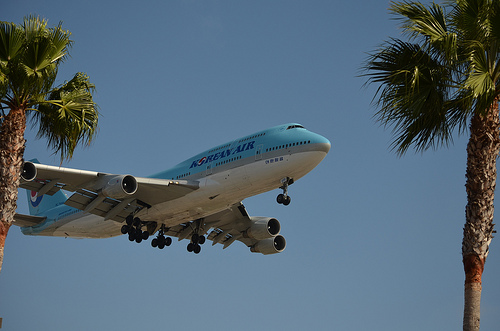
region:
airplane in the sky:
[0, 108, 337, 276]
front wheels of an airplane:
[271, 172, 298, 211]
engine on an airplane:
[94, 169, 146, 203]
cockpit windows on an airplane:
[281, 120, 312, 136]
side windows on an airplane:
[212, 149, 249, 169]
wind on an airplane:
[11, 150, 203, 227]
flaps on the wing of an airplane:
[58, 184, 151, 234]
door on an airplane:
[249, 141, 268, 168]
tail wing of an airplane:
[5, 205, 45, 233]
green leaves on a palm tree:
[35, 66, 102, 169]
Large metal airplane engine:
[97, 163, 149, 207]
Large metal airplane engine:
[237, 201, 282, 244]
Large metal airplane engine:
[246, 232, 290, 259]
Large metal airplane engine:
[10, 156, 52, 192]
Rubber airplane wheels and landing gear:
[262, 175, 301, 214]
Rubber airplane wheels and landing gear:
[177, 219, 211, 261]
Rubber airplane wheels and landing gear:
[150, 219, 177, 256]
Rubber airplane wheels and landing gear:
[118, 212, 154, 249]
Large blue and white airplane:
[0, 102, 362, 292]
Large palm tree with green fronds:
[362, 1, 498, 329]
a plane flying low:
[16, 11, 481, 321]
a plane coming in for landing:
[4, 8, 491, 328]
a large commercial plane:
[12, 98, 361, 279]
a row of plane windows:
[266, 135, 321, 153]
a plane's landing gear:
[115, 211, 216, 260]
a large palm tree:
[367, 2, 497, 310]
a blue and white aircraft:
[0, 110, 352, 276]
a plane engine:
[98, 163, 152, 205]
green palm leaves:
[2, 21, 119, 146]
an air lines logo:
[182, 132, 261, 176]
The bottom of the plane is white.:
[249, 157, 354, 186]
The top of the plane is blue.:
[244, 127, 281, 162]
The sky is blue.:
[158, 70, 214, 110]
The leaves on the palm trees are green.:
[9, 67, 50, 90]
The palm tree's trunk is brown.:
[0, 149, 28, 197]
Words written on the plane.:
[192, 139, 264, 178]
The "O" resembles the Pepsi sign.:
[189, 156, 215, 176]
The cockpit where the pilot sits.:
[277, 116, 324, 145]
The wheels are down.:
[142, 238, 217, 260]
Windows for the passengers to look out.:
[250, 132, 326, 163]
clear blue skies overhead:
[131, 31, 336, 81]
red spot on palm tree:
[434, 245, 499, 284]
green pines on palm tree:
[339, 31, 449, 163]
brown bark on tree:
[472, 153, 487, 194]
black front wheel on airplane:
[275, 168, 331, 210]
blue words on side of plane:
[170, 138, 268, 171]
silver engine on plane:
[100, 162, 172, 232]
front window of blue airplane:
[270, 108, 336, 143]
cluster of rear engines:
[98, 198, 250, 290]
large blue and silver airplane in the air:
[25, 97, 358, 264]